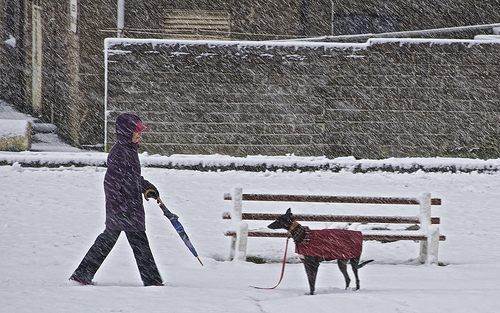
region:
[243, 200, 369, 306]
THE DOG IS STANDING IN THE SNOW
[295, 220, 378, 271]
THE DO IS WEARING A RED DOG SWEATER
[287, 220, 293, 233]
THE DOG IS WEARING A COLLAR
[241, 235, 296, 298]
THE DOG IS ON A LEASH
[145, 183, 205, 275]
THE MAN IS CARRYING AN UMBRELLA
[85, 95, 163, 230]
THE MAN'S COAT HAS A HOOD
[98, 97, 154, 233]
THE MAN IS WEARING A BLUE COAT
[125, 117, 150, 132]
THE MAN IS WEARING A RED HAT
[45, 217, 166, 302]
THE MAN IS WEARING BLACK PANTS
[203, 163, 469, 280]
THE BENCH HAS SNOW ON IT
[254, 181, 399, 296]
dog on the ground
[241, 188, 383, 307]
dog in the snow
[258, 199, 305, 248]
head of the dog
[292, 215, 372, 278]
red outfit on dog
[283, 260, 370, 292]
legs on the dog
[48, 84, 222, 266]
person next to dog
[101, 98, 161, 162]
hood on the person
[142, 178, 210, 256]
item in person's hand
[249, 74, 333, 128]
wall in the background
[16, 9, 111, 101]
snow in the air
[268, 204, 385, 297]
dog on a leash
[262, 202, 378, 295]
dog with a blanket on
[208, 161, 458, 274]
bench in the snow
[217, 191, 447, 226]
back of the bench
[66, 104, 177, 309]
boy in the snow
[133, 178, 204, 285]
umbrella in the boy's hand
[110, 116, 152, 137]
hat on the boy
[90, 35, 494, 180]
wall behind the boy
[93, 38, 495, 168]
bricks in the wall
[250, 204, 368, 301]
a dog in front of the bench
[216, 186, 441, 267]
the bench is snow-covered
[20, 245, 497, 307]
the path is covered in snow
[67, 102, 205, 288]
a person walking in the snow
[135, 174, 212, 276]
the person is carrying an umbrella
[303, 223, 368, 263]
the dog has a red blanket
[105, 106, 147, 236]
the jacket is purple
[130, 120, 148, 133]
the hood is red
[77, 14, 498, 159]
wall behind the bench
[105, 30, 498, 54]
snow on the wall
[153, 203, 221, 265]
an umbrella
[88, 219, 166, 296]
person wearing pants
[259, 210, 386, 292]
a dog standing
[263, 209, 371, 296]
a dog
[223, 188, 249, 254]
snow on the bench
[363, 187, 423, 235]
the bench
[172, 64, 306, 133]
a brick wall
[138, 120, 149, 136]
women is wearing a pink hat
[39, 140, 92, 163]
snow on the sidewalk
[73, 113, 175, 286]
the women is walking